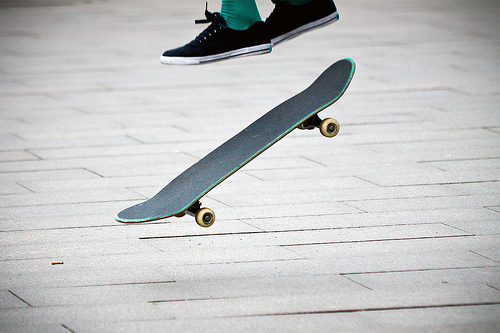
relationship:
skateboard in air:
[114, 58, 354, 225] [96, 0, 390, 249]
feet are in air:
[156, 1, 343, 64] [96, 0, 390, 249]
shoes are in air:
[161, 3, 337, 65] [96, 0, 390, 249]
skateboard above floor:
[114, 58, 354, 225] [1, 3, 499, 332]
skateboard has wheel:
[114, 58, 354, 225] [195, 208, 212, 226]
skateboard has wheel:
[114, 58, 354, 225] [175, 210, 185, 217]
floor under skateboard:
[1, 3, 499, 332] [114, 58, 354, 225]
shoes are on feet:
[161, 3, 337, 65] [156, 1, 343, 64]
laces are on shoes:
[194, 4, 223, 28] [161, 3, 337, 65]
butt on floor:
[50, 260, 65, 264] [1, 3, 499, 332]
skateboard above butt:
[114, 58, 354, 225] [50, 260, 65, 264]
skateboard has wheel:
[114, 58, 354, 225] [323, 119, 340, 135]